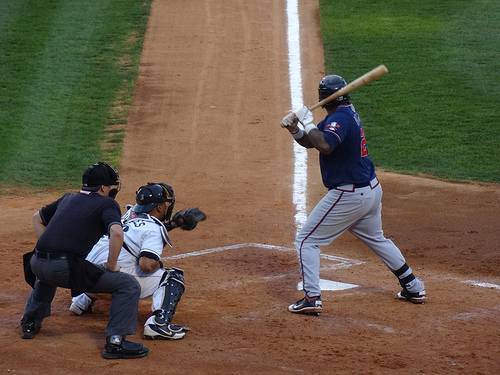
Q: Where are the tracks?
A: On the red clay.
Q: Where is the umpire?
A: Behind the catcher.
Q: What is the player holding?
A: A bat.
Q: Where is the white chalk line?
A: On a baseball field.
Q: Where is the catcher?
A: Behind the hitter.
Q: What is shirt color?
A: Blue.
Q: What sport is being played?
A: Baseball.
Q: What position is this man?
A: Catcher.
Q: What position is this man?
A: Umpire.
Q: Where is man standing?
A: Home plate.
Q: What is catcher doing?
A: Crouching.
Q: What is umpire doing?
A: Crouching.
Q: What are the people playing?
A: Baseball.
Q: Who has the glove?
A: The catcher.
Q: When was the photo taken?
A: Daytime.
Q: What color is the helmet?
A: Black.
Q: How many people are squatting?
A: Two.